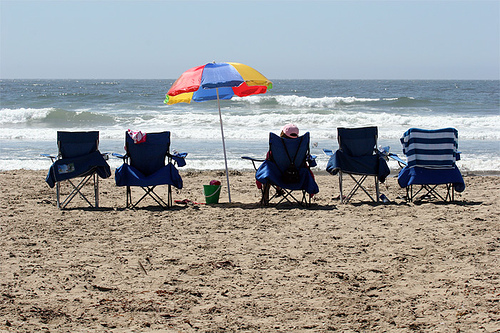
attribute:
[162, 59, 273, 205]
umbrella — tall, blue, leaning to side, red, yellow, stuck, used for shade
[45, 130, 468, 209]
chairs — lined up, in a row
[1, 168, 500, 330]
sand — full of foot tracks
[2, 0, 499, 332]
beach — sandy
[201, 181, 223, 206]
sand pail — green, small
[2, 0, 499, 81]
sky — clear, blue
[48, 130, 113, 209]
chair — blue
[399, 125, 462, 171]
towel — striped, blue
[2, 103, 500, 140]
waves — rolling in, coming in to shore, small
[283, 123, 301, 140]
cap — pink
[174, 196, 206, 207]
flip flops — red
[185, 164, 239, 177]
mound of sand — little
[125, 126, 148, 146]
cloth — little